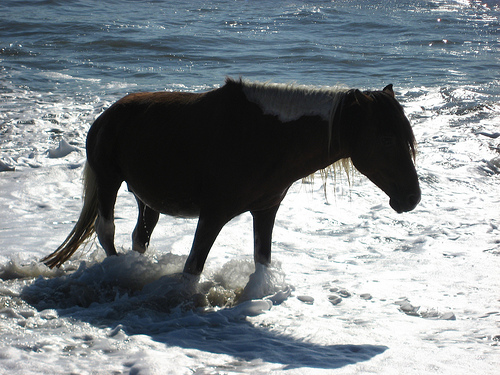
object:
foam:
[37, 67, 103, 89]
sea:
[0, 0, 500, 373]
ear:
[380, 81, 397, 97]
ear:
[351, 86, 376, 111]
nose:
[402, 181, 422, 213]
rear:
[84, 89, 159, 176]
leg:
[180, 213, 229, 284]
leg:
[249, 205, 279, 265]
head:
[343, 82, 423, 214]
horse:
[36, 75, 423, 289]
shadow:
[20, 256, 390, 369]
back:
[88, 88, 197, 134]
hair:
[323, 82, 417, 167]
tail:
[32, 151, 102, 268]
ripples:
[48, 52, 342, 77]